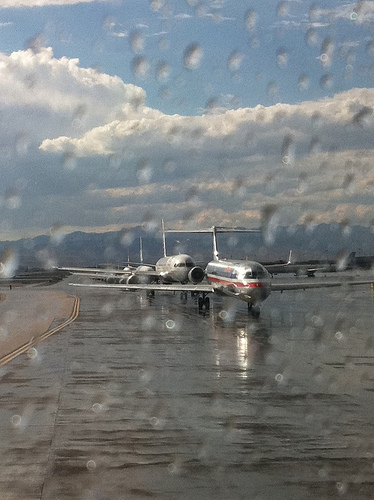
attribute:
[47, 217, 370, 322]
airplanes — silver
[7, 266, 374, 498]
road — wet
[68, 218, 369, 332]
airplane — red, blue, white,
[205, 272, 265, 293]
stripe — red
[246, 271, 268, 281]
window — wet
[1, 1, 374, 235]
sky — blue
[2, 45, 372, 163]
clouds — grey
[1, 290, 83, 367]
lines — yellow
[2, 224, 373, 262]
mountains — tall